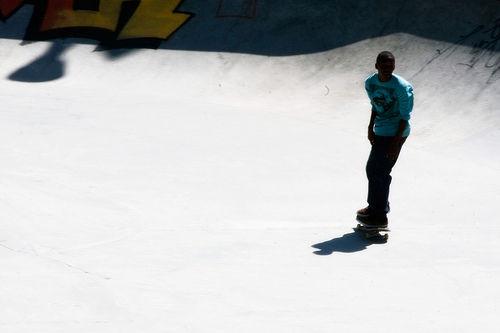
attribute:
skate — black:
[354, 222, 393, 245]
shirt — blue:
[363, 72, 415, 141]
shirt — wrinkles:
[363, 74, 413, 138]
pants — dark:
[353, 122, 412, 233]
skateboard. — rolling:
[326, 190, 414, 250]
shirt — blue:
[342, 62, 429, 147]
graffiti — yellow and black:
[20, 0, 190, 47]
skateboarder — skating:
[347, 42, 419, 247]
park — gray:
[1, 2, 497, 332]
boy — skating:
[353, 49, 413, 227]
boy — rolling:
[358, 45, 414, 222]